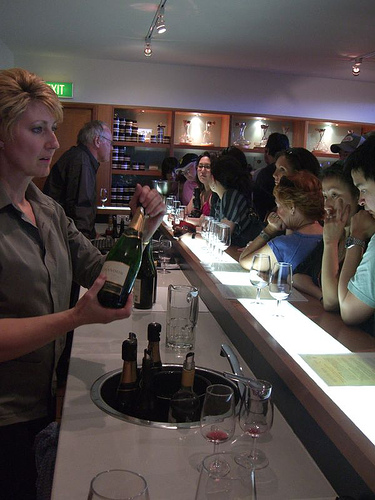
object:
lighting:
[155, 22, 169, 37]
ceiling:
[0, 3, 374, 91]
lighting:
[348, 56, 365, 78]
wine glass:
[193, 451, 250, 500]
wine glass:
[195, 383, 237, 481]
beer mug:
[163, 280, 201, 356]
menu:
[294, 349, 373, 391]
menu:
[215, 282, 315, 308]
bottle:
[94, 197, 150, 311]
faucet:
[216, 343, 256, 412]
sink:
[87, 357, 249, 431]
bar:
[0, 97, 374, 497]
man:
[43, 118, 113, 246]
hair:
[76, 117, 107, 145]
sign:
[34, 75, 75, 100]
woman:
[0, 66, 170, 498]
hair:
[0, 67, 63, 141]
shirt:
[261, 227, 323, 285]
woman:
[183, 150, 222, 223]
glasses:
[193, 163, 214, 170]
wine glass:
[269, 263, 293, 327]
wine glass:
[245, 250, 271, 310]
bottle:
[113, 330, 146, 417]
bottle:
[167, 351, 202, 425]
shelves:
[0, 101, 375, 208]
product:
[115, 119, 168, 143]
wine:
[197, 382, 243, 477]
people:
[336, 138, 374, 328]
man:
[178, 151, 200, 206]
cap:
[173, 151, 199, 175]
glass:
[213, 221, 232, 272]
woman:
[238, 167, 325, 289]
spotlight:
[350, 60, 365, 78]